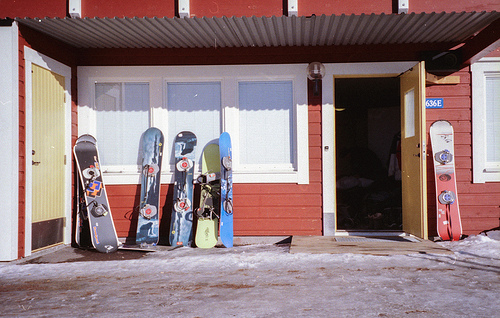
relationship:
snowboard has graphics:
[209, 135, 250, 209] [79, 161, 115, 191]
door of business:
[322, 59, 450, 203] [149, 42, 478, 212]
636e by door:
[418, 97, 451, 115] [322, 59, 450, 203]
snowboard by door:
[209, 135, 250, 209] [322, 59, 450, 203]